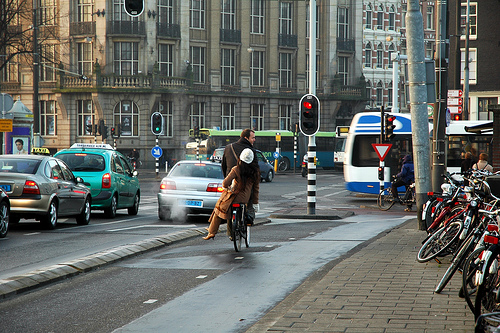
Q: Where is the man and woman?
A: On a bike.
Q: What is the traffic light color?
A: Red.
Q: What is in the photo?
A: Cars.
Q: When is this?
A: Daytime.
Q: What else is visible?
A: Buildings.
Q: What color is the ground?
A: Gray.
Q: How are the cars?
A: In motion.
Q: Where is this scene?
A: On the street.